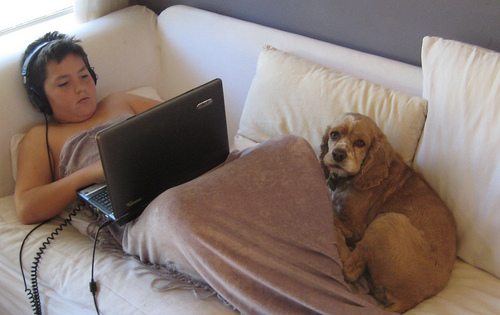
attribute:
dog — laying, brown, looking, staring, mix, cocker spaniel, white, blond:
[320, 113, 457, 314]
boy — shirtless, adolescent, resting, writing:
[16, 34, 164, 226]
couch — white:
[6, 6, 498, 314]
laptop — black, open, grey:
[78, 78, 234, 225]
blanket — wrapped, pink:
[63, 113, 374, 313]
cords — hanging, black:
[20, 200, 112, 313]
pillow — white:
[236, 47, 431, 163]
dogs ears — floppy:
[319, 127, 392, 190]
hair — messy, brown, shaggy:
[19, 31, 89, 115]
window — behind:
[0, 0, 79, 58]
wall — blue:
[135, 2, 499, 67]